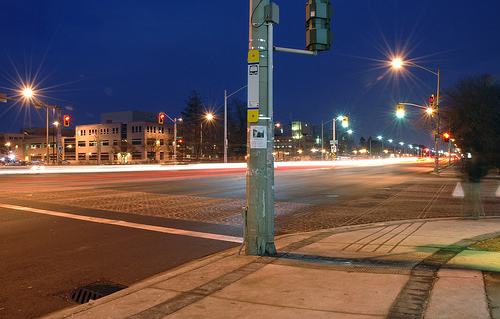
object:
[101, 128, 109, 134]
window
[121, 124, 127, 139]
window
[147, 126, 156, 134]
window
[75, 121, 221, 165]
building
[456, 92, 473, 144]
leaves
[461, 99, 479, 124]
leaves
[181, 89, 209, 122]
leaves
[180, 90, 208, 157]
tree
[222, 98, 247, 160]
tree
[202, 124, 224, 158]
leaves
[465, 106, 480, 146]
leaves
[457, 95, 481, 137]
leaves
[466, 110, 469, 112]
leaf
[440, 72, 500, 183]
plant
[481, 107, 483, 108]
leaf